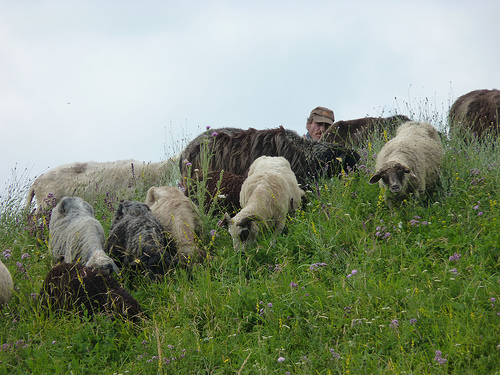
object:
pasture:
[0, 87, 500, 375]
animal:
[178, 127, 362, 188]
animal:
[35, 262, 149, 325]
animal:
[24, 158, 174, 223]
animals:
[222, 156, 305, 256]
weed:
[425, 252, 446, 284]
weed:
[407, 322, 451, 370]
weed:
[455, 201, 480, 229]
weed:
[375, 222, 423, 243]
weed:
[300, 262, 343, 288]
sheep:
[146, 185, 197, 257]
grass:
[0, 147, 494, 372]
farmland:
[0, 337, 497, 372]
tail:
[25, 185, 36, 216]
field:
[8, 69, 470, 361]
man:
[301, 106, 336, 141]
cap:
[307, 106, 335, 125]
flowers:
[0, 207, 500, 370]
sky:
[0, 0, 500, 183]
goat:
[49, 196, 120, 277]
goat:
[368, 122, 444, 210]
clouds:
[45, 14, 383, 86]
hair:
[209, 145, 232, 166]